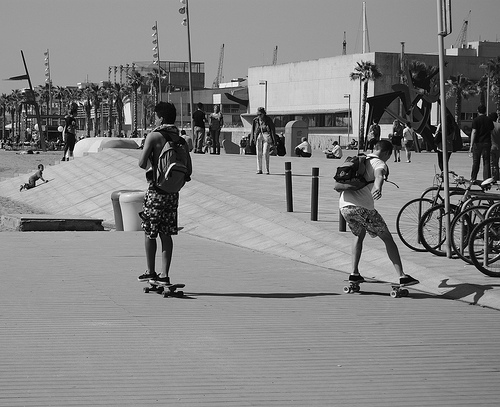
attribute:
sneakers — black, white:
[343, 271, 422, 291]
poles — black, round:
[278, 157, 323, 223]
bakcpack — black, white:
[143, 124, 194, 210]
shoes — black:
[138, 270, 169, 285]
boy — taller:
[330, 130, 417, 300]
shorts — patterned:
[137, 187, 187, 245]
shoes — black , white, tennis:
[133, 266, 178, 290]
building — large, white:
[262, 37, 493, 155]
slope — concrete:
[4, 148, 144, 228]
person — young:
[323, 138, 413, 276]